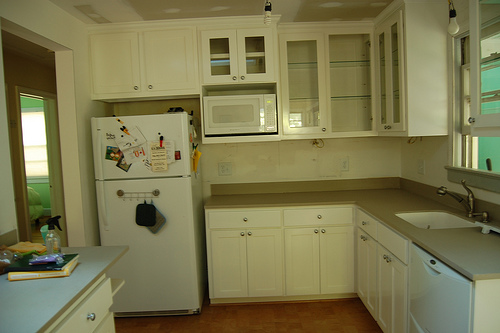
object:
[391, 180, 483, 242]
sink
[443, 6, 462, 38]
light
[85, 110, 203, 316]
fridge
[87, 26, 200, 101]
cabinets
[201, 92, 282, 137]
microwave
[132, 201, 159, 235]
pot holder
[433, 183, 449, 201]
faucet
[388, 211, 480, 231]
sink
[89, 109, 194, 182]
freezer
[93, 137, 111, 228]
handle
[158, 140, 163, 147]
magnet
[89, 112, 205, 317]
refrigerator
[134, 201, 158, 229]
hot pad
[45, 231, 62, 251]
bottle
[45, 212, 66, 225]
nozzel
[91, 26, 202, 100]
cubby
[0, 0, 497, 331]
kitchen